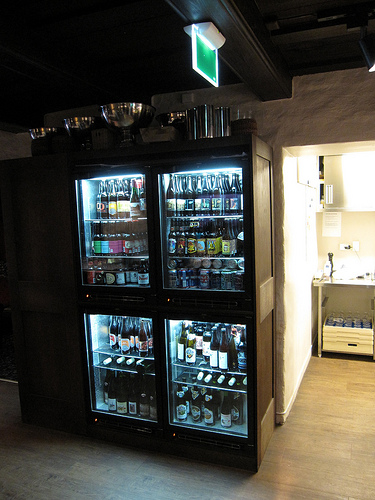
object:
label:
[108, 398, 116, 410]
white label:
[129, 401, 137, 414]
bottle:
[168, 217, 177, 256]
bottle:
[228, 328, 237, 370]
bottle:
[202, 323, 211, 362]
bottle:
[177, 176, 186, 217]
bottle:
[237, 326, 248, 372]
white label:
[196, 335, 203, 349]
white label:
[204, 408, 214, 424]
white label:
[178, 342, 184, 359]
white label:
[109, 334, 116, 346]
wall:
[299, 75, 370, 131]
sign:
[191, 23, 219, 89]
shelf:
[172, 355, 247, 378]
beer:
[96, 182, 103, 219]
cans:
[233, 270, 244, 290]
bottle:
[182, 377, 191, 415]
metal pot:
[186, 104, 232, 141]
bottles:
[187, 218, 197, 257]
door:
[251, 135, 276, 474]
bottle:
[201, 175, 210, 216]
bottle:
[165, 174, 176, 217]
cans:
[227, 259, 237, 268]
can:
[200, 269, 210, 289]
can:
[220, 269, 231, 290]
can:
[211, 271, 220, 288]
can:
[168, 269, 178, 288]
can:
[179, 269, 189, 289]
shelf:
[168, 256, 244, 261]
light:
[191, 24, 218, 87]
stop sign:
[217, 345, 228, 371]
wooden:
[323, 331, 373, 353]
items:
[323, 315, 371, 326]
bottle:
[229, 173, 240, 216]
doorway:
[281, 140, 375, 423]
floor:
[0, 355, 375, 500]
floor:
[9, 444, 55, 485]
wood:
[300, 408, 371, 473]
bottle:
[195, 176, 202, 216]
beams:
[165, 0, 292, 103]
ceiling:
[0, 0, 375, 113]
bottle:
[221, 396, 232, 429]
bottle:
[185, 176, 194, 217]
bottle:
[204, 389, 215, 425]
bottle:
[209, 326, 220, 369]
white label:
[202, 340, 210, 356]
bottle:
[219, 328, 230, 372]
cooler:
[67, 132, 275, 472]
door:
[68, 168, 156, 297]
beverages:
[166, 171, 244, 218]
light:
[86, 295, 88, 297]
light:
[168, 299, 170, 301]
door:
[151, 160, 253, 304]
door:
[160, 309, 254, 452]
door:
[79, 304, 163, 435]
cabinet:
[319, 156, 325, 209]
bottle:
[178, 323, 187, 362]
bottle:
[176, 380, 188, 422]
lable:
[176, 404, 187, 419]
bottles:
[176, 218, 185, 257]